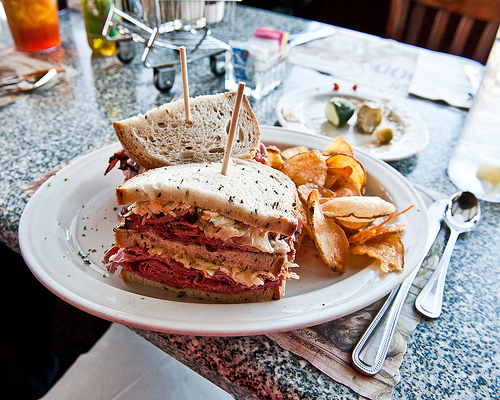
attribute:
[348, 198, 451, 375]
knife — silver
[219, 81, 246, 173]
peg — wood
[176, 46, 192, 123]
peg — wood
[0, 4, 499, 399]
table — black, white, textured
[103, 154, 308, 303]
snadwich — halved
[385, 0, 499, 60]
chair — wood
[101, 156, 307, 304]
sandwich — large, halved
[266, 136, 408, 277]
potato chips — piled, kettle style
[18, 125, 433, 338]
plate — large, round, white, glass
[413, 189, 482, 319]
spoon — silver, reflective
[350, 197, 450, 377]
butter knife — silver, long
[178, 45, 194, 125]
toothpick — wooden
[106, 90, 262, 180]
sandwich — halved, small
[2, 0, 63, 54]
glass — beverage, ice tea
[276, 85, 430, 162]
plate — small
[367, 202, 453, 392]
knife — silver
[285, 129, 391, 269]
chips — kettle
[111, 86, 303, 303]
sandwich — large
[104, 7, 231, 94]
cart — small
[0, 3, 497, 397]
table pattern — blue, white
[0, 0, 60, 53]
tea — iced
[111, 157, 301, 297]
sandwich — large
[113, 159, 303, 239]
bread slice — rye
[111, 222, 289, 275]
bread slice — rye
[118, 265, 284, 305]
bread slice — rye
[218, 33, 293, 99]
container — clear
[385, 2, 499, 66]
chair back — wooden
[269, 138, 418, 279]
chips — crispy, potato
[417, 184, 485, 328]
utensil — spoon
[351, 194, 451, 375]
utensil — knife, silverware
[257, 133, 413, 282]
chips — potato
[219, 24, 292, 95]
holder — sugar packed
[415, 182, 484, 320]
spoon — small, silver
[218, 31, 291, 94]
container — glass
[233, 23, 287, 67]
packets — sugar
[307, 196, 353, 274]
chip — home made, potato